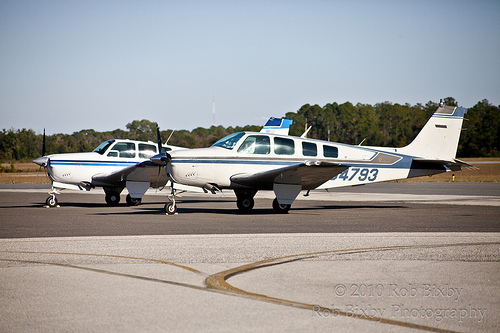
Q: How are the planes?
A: Parked.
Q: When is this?
A: Daytime.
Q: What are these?
A: Planes.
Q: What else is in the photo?
A: Trees.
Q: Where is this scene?
A: An Airfield.